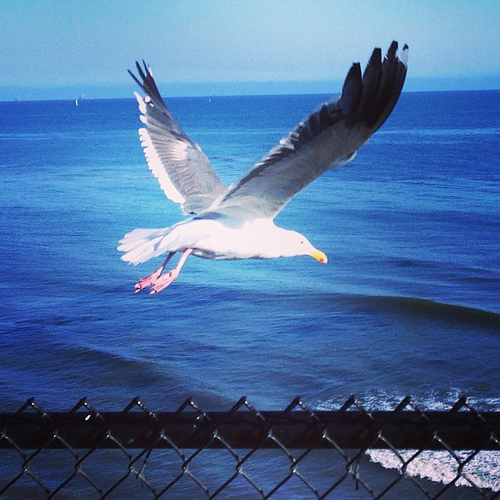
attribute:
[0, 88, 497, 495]
water — white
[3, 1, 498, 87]
sky — blue in color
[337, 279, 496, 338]
wave — small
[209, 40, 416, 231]
wing — long, narrow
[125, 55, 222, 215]
wing — long, narrow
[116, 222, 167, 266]
feathers — tail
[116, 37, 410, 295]
bird — white color, flying in the air, white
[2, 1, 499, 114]
sky — blue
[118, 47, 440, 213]
wings — big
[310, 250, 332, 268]
beak — yellow in color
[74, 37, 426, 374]
bird — white in color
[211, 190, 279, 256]
feathers — white in color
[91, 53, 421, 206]
feathers — black and white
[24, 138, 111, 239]
sea water — blue color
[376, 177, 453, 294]
sea water — blue color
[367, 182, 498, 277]
water — blue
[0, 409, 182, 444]
rod — metal